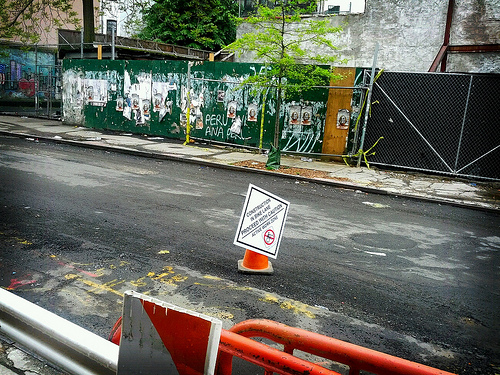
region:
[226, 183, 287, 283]
sign on orange cone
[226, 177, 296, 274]
sign on orange traffic cone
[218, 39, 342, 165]
bright green tree on sidewalk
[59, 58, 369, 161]
green boards with graffiti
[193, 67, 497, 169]
wire fence along sidewalk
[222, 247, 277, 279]
traffic cone is orange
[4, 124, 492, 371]
street is stripped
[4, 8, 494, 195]
area is abandoned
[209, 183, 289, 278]
warning sign on orange traffic cone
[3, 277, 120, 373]
metal railing on side of street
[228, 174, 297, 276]
A sign in the road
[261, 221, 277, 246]
A no bike posting on the white sign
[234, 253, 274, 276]
The orange cone holds the sign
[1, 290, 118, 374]
A guard rail on the side of the road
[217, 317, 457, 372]
The orange rail of the guard rail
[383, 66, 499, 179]
The chain link fence along the sidewalk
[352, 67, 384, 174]
yellow caution tape hanging from the fence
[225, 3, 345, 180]
a tree in the mulch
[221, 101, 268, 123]
posters on the chain link fence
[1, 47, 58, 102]
Graffiti art on the side of a building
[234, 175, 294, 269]
A sign in the street.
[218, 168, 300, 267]
A small sign in the street.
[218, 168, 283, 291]
A small black, white and red sign in the street.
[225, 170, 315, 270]
A black, white and red sign in the street.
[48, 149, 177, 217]
Part of a road.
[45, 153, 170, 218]
Part of a cement road.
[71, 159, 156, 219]
Part of a large cement road.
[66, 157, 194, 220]
Part of a large grey cement road.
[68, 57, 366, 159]
A wall on the sidewalk.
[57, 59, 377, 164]
A wall with photos on the sidewalk.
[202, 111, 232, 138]
tagging on the fence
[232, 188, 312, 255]
a sign in the street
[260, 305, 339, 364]
an orange railing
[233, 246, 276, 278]
an orange cone in the street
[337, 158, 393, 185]
the sidewalk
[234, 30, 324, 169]
a green tree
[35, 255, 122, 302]
yellow marking on the street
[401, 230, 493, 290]
water on the street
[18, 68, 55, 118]
a fence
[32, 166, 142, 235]
the street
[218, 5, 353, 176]
bright green folage in the middle of sidewalk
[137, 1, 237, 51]
healthy tree full of leaves in city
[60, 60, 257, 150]
various posters lining construction fence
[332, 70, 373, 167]
yellow caution construction zone tape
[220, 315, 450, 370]
orange guard rails for construction project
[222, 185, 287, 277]
construction caution sign for drivers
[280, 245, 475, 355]
recent road work being done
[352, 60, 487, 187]
construction fencing black and steel pipes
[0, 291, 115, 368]
new white guard rail on side of road work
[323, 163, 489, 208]
old patched sidewalk among construction project